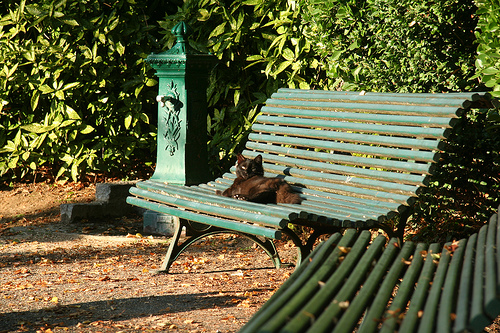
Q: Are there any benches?
A: Yes, there is a bench.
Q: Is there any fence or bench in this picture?
A: Yes, there is a bench.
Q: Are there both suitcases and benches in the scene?
A: No, there is a bench but no suitcases.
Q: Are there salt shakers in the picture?
A: No, there are no salt shakers.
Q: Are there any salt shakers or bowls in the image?
A: No, there are no salt shakers or bowls.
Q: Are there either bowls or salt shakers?
A: No, there are no salt shakers or bowls.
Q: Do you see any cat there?
A: Yes, there is a cat.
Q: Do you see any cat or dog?
A: Yes, there is a cat.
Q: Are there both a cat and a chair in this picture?
A: No, there is a cat but no chairs.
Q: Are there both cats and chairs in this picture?
A: No, there is a cat but no chairs.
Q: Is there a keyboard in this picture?
A: No, there are no keyboards.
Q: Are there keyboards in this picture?
A: No, there are no keyboards.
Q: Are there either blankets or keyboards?
A: No, there are no keyboards or blankets.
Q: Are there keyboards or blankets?
A: No, there are no keyboards or blankets.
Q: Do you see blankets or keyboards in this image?
A: No, there are no keyboards or blankets.